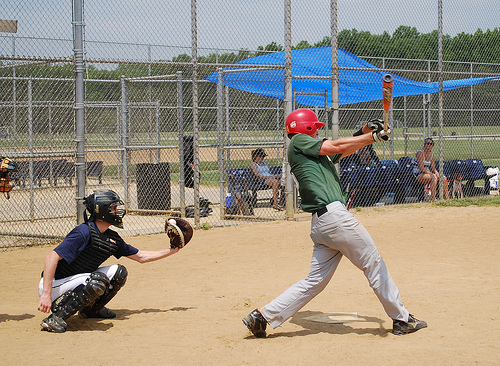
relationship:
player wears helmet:
[241, 104, 426, 338] [279, 101, 326, 137]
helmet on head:
[82, 186, 123, 216] [81, 183, 128, 228]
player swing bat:
[233, 104, 433, 338] [377, 74, 395, 139]